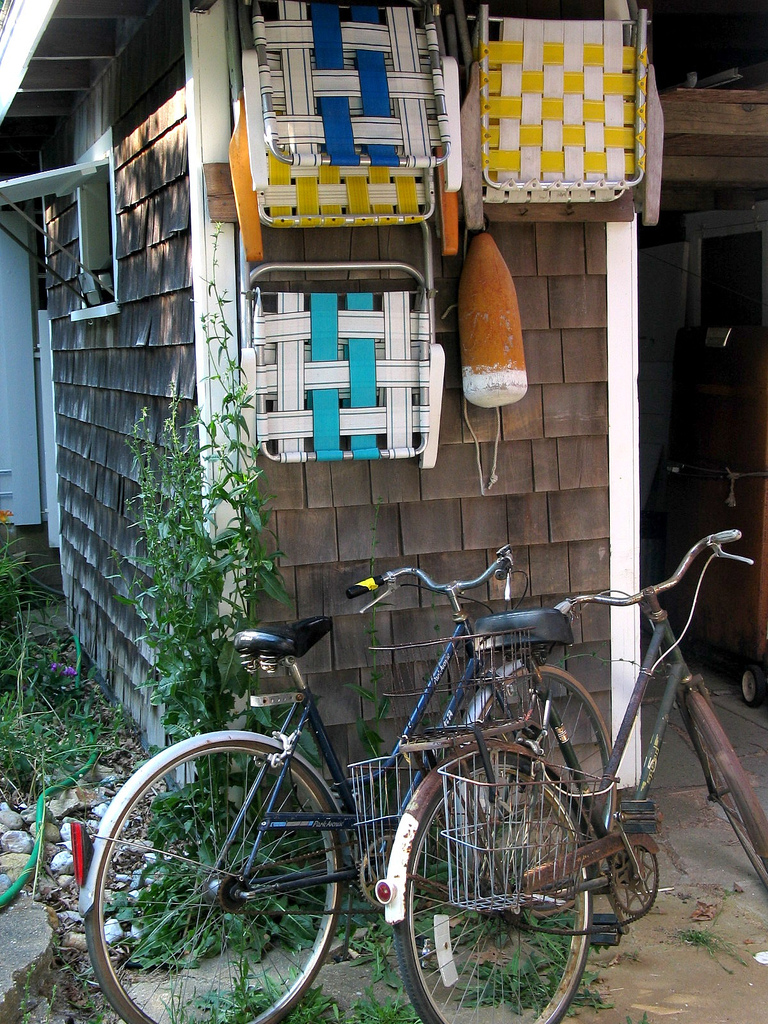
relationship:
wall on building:
[259, 271, 605, 836] [26, 70, 662, 871]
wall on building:
[253, 468, 367, 634] [47, 38, 636, 910]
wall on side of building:
[257, 455, 398, 562] [240, 46, 615, 618]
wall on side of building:
[250, 569, 340, 643] [208, 127, 604, 667]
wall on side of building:
[257, 569, 386, 652] [207, 32, 637, 692]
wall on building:
[263, 516, 353, 585] [215, 162, 631, 659]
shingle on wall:
[471, 450, 532, 501] [466, 466, 577, 566]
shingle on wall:
[424, 444, 471, 492] [507, 485, 562, 560]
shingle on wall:
[399, 502, 491, 553] [278, 466, 462, 586]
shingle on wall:
[326, 505, 415, 570] [301, 490, 504, 575]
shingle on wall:
[269, 497, 354, 575] [313, 462, 428, 549]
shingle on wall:
[302, 464, 391, 510] [284, 491, 588, 615]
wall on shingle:
[280, 469, 520, 579] [266, 457, 341, 512]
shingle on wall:
[253, 459, 338, 526] [417, 432, 601, 575]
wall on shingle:
[526, 335, 580, 409] [394, 434, 561, 547]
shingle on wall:
[521, 270, 546, 328] [389, 485, 523, 545]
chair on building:
[202, 216, 460, 477] [0, 0, 642, 901]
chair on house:
[473, 23, 665, 228] [378, 439, 580, 584]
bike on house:
[129, 575, 564, 945] [389, 453, 587, 563]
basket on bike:
[456, 758, 609, 910] [248, 580, 616, 916]